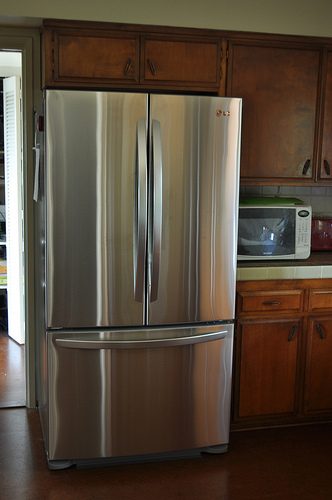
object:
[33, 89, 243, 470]
refrigerator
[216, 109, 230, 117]
logo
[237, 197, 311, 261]
microwave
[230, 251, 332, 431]
counter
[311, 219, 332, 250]
canister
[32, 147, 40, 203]
paper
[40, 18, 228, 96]
cabinet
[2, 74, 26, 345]
door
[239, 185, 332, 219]
backsplash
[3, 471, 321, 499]
floor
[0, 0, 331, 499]
kitchen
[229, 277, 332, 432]
cabinets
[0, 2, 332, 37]
wall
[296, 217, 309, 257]
control panel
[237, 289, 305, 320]
drawer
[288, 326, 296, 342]
handle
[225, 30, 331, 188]
cabinet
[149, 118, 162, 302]
handle